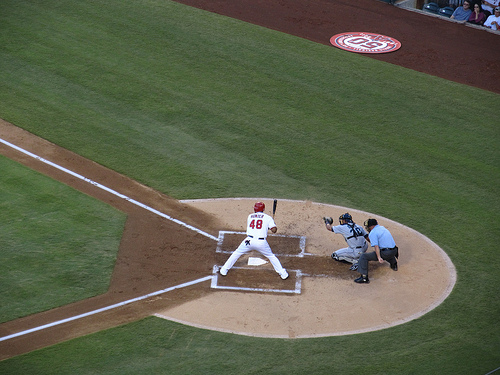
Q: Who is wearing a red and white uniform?
A: Batter.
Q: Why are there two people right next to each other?
A: Umpire calling strikes.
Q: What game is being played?
A: Baseball.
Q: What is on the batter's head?
A: A helmet.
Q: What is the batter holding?
A: A bat.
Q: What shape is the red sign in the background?
A: Round.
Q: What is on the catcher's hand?
A: A glove.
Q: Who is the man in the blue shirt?
A: An umpire.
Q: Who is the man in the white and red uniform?
A: The batter.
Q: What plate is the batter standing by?
A: Homeplate.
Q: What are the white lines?
A: Foul lines.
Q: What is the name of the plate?
A: The plate name is home plate.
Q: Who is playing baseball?
A: The three people.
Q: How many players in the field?
A: Three.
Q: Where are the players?
A: In the field.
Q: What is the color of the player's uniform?
A: White.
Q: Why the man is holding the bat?
A: To hit the ball.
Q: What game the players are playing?
A: Baseball.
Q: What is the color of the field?
A: Brown and green.